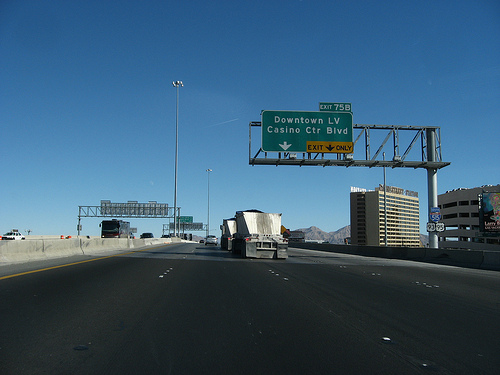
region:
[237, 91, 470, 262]
A road sign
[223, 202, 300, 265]
A truck on a highway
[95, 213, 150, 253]
A bus on a highway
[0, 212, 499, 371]
A highway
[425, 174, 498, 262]
A parking garage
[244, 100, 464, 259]
A road sign on a highway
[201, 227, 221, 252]
A car driving on a highway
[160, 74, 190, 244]
A light post on a highway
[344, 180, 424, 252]
A building next to a highway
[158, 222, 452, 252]
A mountain range in the distance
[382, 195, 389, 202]
window of a building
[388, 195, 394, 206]
window of a building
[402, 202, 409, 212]
window of a building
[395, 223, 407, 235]
window of a building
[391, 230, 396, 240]
window of a building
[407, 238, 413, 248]
window of a building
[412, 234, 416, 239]
window of a building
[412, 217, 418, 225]
window of a building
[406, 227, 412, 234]
window of a building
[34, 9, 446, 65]
a blue sky in the background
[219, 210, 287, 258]
a couple of trucks on the road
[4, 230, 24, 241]
looks like a police car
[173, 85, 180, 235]
a vertical metal tube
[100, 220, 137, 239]
another truck on the scene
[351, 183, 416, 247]
a huge white building to the right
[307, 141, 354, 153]
it says exit only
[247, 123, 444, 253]
a very strong metal structure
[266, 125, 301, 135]
the word Casino in white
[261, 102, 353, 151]
a sign indicating location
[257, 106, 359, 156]
GREEN HANGING HIGHWAY SIGN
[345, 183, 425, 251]
TALL BUILDINGS IN BACKGROUND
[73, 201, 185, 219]
OVERHEAD SIGN SUPPORT IN OPPOSITE LANE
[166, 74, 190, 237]
OVERHEAD HIGHWAY LIGHTS ON POLE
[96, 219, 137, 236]
LARGE VEHICLE IN OPPOSITE LANE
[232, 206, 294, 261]
LARGE VEHICLE IN AHEAD TRAFFIC LANE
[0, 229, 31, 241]
WHITE VEHICLE IN OPPOSITE LANE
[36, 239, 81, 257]
CONCRED BARRIDADE DIVIDING TRAFFIC LANES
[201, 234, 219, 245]
VEHICLE DRIVING IN AHEAD TRAFFIC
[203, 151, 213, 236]
OVERHEAD LIGHT ON TALL POLE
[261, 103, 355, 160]
A green and white sign.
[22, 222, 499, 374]
The road.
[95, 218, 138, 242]
A large tour bus.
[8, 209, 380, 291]
Vehicles on the road.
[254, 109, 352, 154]
sign on the pole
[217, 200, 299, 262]
truck on the road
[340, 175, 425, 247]
building in the distance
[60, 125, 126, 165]
the sky is clear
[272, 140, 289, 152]
arrow on the sign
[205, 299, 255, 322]
the street is black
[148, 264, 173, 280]
lines on the road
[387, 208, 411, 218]
windows on the building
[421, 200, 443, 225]
sign on the pole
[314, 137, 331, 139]
the sign is green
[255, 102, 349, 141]
a green and white street sign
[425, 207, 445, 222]
a blue white and red street sign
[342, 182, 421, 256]
a tall building with several levels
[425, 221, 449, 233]
two black and white road signs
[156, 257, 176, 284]
white lines painted on a interstate highway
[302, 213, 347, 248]
grey mountains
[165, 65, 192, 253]
a tall metal street light